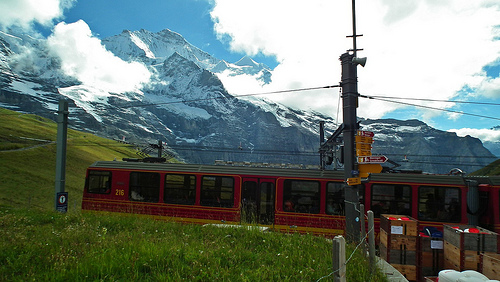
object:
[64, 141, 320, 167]
tracks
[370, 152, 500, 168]
train tracks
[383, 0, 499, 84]
sky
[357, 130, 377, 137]
sign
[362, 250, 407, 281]
curb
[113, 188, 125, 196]
216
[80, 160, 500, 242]
train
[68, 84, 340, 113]
line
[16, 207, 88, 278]
grass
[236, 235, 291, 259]
flowers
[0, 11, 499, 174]
mountains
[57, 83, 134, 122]
snow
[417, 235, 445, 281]
boxes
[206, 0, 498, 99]
cloud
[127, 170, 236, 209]
windows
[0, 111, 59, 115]
wires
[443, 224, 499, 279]
crates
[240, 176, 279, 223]
door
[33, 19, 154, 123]
clouds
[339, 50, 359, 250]
pole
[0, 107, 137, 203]
ground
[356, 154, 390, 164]
sign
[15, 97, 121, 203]
hills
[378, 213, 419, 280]
box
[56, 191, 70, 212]
sign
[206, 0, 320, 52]
sky